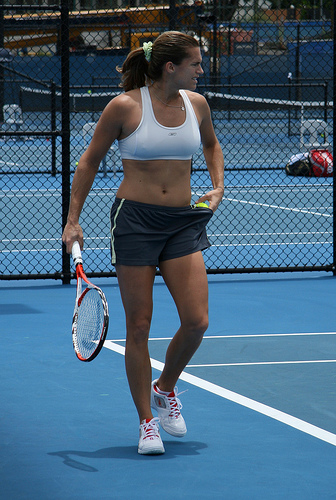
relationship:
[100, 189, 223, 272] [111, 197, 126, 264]
shorts with stripe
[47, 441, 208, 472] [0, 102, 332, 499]
shadow cast on floor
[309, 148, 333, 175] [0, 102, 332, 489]
bag on floor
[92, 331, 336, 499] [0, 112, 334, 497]
line on tennis court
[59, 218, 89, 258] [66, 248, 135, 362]
hand holding racket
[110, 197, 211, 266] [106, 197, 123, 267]
shorts with stripe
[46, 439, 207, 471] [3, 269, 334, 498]
shadow on tennis court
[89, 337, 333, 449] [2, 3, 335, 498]
line on tennis court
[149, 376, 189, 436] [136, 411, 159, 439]
shoe with pins